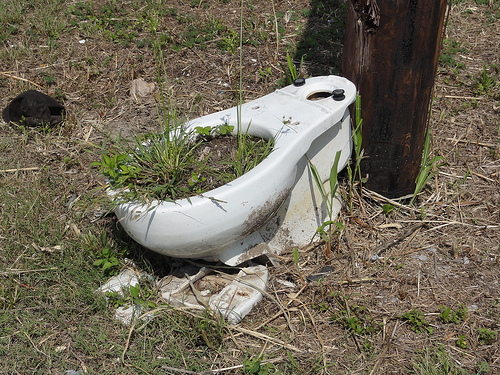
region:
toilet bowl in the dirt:
[96, 53, 364, 281]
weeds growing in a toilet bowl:
[148, 122, 243, 187]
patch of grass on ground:
[403, 310, 428, 332]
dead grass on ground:
[16, 281, 75, 358]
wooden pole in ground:
[326, 6, 451, 200]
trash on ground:
[111, 251, 286, 331]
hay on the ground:
[400, 194, 464, 228]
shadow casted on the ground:
[296, 6, 348, 68]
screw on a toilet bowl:
[328, 81, 348, 107]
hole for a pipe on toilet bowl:
[306, 84, 330, 107]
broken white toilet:
[84, 55, 369, 277]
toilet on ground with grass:
[71, 43, 388, 336]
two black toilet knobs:
[288, 68, 346, 107]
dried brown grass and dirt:
[355, 201, 487, 305]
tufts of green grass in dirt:
[318, 294, 475, 343]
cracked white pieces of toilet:
[136, 250, 281, 322]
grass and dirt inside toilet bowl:
[98, 96, 276, 257]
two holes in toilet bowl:
[243, 94, 305, 144]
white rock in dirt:
[108, 54, 173, 113]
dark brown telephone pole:
[361, 8, 441, 229]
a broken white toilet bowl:
[103, 74, 355, 270]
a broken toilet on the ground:
[73, 0, 355, 267]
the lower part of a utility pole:
[343, 1, 453, 200]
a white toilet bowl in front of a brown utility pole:
[105, 0, 450, 269]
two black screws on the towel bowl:
[292, 77, 344, 101]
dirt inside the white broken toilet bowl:
[200, 141, 237, 178]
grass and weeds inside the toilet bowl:
[92, 114, 279, 205]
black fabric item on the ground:
[2, 85, 63, 128]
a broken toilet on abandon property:
[105, 75, 358, 268]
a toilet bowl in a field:
[70, 72, 496, 372]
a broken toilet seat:
[68, 59, 388, 291]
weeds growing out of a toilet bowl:
[118, 113, 263, 208]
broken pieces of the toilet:
[97, 263, 282, 331]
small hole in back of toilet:
[306, 81, 334, 103]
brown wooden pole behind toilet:
[284, 0, 456, 208]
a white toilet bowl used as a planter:
[91, 71, 378, 291]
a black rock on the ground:
[11, 86, 72, 138]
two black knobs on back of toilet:
[291, 72, 353, 111]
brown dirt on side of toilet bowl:
[235, 197, 305, 259]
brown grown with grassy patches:
[8, 6, 499, 373]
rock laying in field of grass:
[112, 60, 175, 115]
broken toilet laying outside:
[103, 47, 371, 273]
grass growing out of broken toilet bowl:
[90, 82, 305, 227]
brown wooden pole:
[333, 0, 440, 209]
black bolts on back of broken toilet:
[282, 72, 359, 109]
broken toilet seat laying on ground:
[85, 257, 292, 331]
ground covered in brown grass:
[357, 190, 499, 301]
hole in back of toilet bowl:
[297, 83, 337, 104]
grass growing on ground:
[15, 0, 142, 40]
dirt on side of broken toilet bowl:
[246, 200, 303, 257]